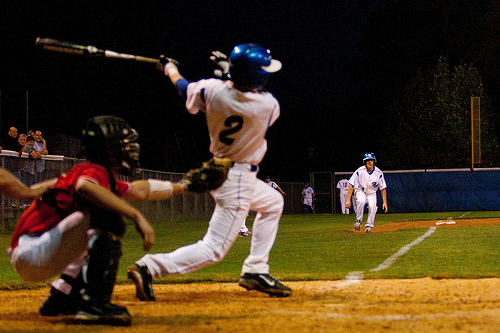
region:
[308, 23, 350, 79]
this is the sky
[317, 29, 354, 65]
the sky is dark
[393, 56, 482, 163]
this is a tree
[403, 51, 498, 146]
the tree is short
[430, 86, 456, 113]
the leaves are green in color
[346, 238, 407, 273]
this is the grass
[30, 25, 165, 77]
this is a bat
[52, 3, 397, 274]
these are baseball players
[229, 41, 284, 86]
this is a helmet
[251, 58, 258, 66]
the helmet is blue in color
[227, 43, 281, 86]
Blue baseball helmet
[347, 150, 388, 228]
Baseball player playing baseball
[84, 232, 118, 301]
Shin guard on a leg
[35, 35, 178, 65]
A baseball bat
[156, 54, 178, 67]
Glove worn by baseball player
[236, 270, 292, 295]
A Nike cleat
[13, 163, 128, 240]
Red baseball jersey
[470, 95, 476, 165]
Foul ball pole that is yellow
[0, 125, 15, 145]
Man wearing a black shirt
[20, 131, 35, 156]
Person wearing a green shirt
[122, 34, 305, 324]
child swinging base ball bat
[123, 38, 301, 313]
child playing softball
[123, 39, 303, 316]
child with the number 2 on back of his shirt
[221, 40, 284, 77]
batters blue helmet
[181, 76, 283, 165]
batters shirt with the number 2 on it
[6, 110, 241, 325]
child behind the batter ready to catch a ball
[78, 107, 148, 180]
face mask of child ready to catch ball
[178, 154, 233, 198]
baseball mitt of child ready to catch ball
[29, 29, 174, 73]
baseball bat of the child with the number 2 on back of his shirt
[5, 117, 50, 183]
fans watching the game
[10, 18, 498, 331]
men are playing base ball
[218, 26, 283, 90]
the helmet is blue in colour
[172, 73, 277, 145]
the jersey is white in colour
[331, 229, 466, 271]
the grass is geen in color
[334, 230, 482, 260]
the grass has a white stripes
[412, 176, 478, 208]
thewall is blue in colour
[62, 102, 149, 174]
the helmet is black in colour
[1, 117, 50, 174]
the spectators are watching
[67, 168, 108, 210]
the jersey is red in colour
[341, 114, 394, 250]
theman is bent